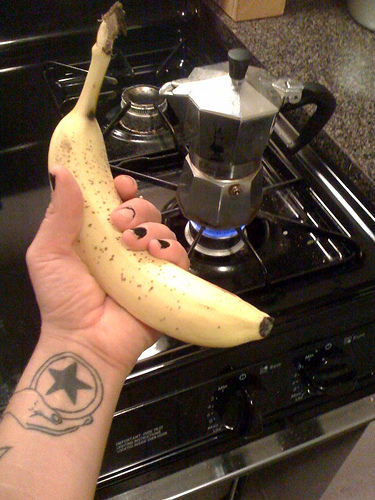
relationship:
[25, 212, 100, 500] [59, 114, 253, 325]
hand holding bannana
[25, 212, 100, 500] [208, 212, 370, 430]
hand near stove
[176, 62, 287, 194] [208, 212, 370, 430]
pot on stove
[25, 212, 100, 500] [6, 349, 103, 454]
hand has tattoo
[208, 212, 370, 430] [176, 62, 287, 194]
stove has pot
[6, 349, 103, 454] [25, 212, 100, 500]
tattoo on hand